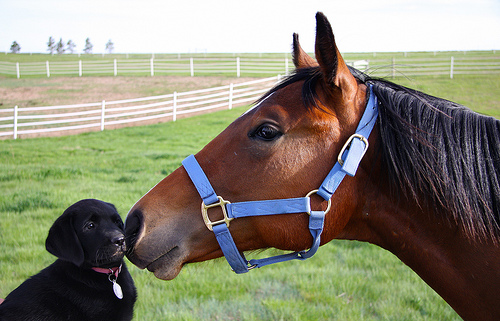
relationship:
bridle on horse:
[222, 190, 326, 264] [121, 1, 479, 285]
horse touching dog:
[121, 1, 479, 285] [1, 165, 123, 313]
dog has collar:
[1, 165, 123, 313] [88, 264, 128, 283]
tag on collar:
[108, 284, 131, 299] [88, 264, 128, 283]